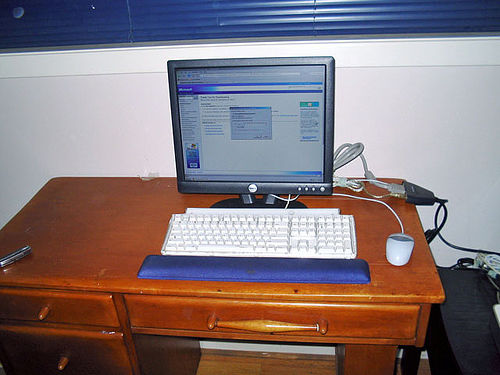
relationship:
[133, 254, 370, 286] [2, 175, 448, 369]
pad on desk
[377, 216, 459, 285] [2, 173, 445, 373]
computer mouse on table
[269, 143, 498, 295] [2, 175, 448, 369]
wire on desk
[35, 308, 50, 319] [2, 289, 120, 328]
knob on drawer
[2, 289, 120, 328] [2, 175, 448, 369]
drawer on left of desk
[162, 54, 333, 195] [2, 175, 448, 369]
monitor on desk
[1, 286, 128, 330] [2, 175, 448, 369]
door in desk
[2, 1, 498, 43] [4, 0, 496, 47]
blinds are on window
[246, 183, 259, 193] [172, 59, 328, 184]
silver button on monitor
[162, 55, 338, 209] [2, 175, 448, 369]
computer monitor on desk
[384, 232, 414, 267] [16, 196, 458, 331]
computer mouse on desk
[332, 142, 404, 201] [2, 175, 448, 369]
cables on desk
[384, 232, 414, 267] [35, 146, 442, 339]
computer mouse on desk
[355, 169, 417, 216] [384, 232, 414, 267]
wire on computer mouse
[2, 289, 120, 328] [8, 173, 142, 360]
drawer on desk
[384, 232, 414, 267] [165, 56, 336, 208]
computer mouse for computer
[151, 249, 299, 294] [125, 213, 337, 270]
pad for keyboard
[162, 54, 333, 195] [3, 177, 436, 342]
monitor on table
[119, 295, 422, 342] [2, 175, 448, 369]
desk drawer on a desk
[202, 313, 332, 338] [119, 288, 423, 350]
handle on a drawer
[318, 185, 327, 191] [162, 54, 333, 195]
button on a monitor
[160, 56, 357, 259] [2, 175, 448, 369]
computer on desk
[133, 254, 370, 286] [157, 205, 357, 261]
pad ini front of keyboard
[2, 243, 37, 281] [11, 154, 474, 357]
item sits on desk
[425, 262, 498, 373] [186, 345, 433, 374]
tower sitting on floor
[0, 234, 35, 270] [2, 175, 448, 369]
army knife on desk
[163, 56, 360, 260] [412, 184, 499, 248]
computer has hook up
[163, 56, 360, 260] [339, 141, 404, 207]
computer has hook up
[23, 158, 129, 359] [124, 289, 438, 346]
desk has drawer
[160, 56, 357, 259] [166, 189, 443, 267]
computer has keyboard